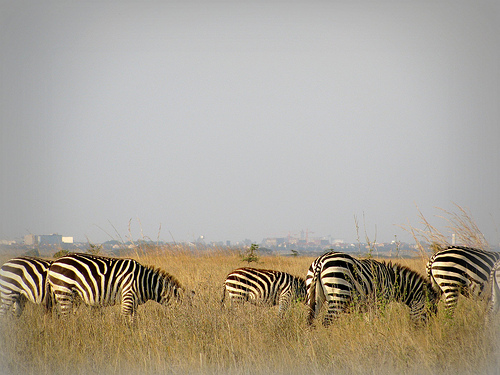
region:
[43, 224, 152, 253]
cities in the distance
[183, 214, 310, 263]
cities in the distance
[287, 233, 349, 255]
cities in the distance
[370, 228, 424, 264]
cities in the distance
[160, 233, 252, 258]
cities in the distance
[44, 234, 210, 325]
brown and white stripes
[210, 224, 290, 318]
brown and white stripes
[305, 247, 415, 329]
brown and white stripes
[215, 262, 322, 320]
brown and white stripes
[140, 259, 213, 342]
the zebra is eating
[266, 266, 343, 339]
the zebra is eating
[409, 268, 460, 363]
the zebra is eating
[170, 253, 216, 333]
the zebra is eating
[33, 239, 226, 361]
zebra's fur is stripes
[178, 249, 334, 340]
zebra's fur is stripes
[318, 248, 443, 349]
zebra's fur is stripes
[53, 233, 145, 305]
zebra's fur is stripes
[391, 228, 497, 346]
zebra's fur is stripes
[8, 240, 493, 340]
six zebras are pictured here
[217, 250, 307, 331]
a small zebra is in the middle of the group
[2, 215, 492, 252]
some building and structures are in the background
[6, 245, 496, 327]
the zebras have stripes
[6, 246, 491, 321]
the zebras are grazing in the field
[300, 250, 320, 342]
the zebras tail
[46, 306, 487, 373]
the grass is tall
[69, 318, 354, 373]
the grass is dry and yellow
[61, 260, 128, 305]
the zebras body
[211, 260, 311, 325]
the smallest zebra of the group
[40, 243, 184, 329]
the zebra is eating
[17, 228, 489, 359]
five zebras eating in the wild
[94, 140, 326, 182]
The sky is very cloudy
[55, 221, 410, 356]
This is an animal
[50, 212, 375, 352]
This is a zebra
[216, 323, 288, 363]
The grass is very long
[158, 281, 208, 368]
The grass is yellow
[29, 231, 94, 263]
This is a building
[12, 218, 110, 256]
The building is white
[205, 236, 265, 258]
This is a small tree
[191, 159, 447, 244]
There is nothing in the sky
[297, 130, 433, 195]
There are no planes